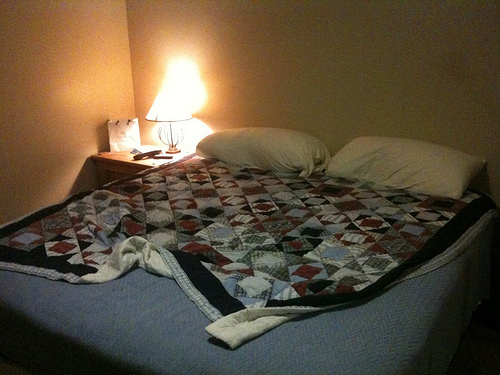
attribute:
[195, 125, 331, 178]
pillow — white, fluffy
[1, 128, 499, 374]
bed — unmade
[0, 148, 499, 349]
bedspread — colorful, patterned, spread, red, white, blue, plaid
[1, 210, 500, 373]
blanket — blue, gray, light blue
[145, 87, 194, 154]
lamp — on, turned on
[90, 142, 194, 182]
table — tan, wooden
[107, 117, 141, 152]
bag — white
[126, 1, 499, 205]
wall — tan, yellow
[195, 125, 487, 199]
pillows — white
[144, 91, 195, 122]
lamp shade — lit up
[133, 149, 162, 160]
remote — black